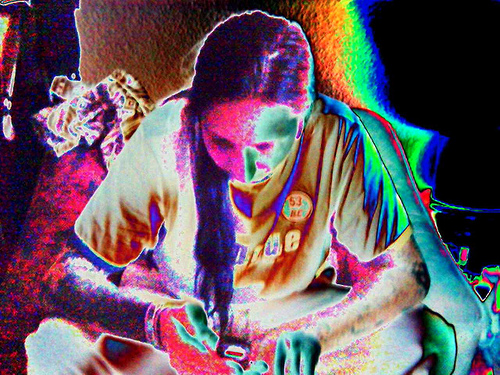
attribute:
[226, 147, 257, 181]
nose — large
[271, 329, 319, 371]
fingers — green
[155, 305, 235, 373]
hand — red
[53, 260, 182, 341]
arm — purple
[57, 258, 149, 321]
spots — blue, pink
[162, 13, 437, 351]
woman — long-haired, dark-haired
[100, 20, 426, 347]
woman — one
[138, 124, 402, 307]
shirt — white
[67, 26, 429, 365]
woman — one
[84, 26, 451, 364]
person — one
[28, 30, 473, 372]
image — distorted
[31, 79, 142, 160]
items — some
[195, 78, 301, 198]
face — female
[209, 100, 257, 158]
spot — pink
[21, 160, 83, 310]
item — pink, blue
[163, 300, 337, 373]
hands — blue, pale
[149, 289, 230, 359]
hand — human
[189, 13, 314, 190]
head — human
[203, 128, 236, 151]
eye — human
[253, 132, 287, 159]
eye — human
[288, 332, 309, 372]
finger — human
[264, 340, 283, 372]
finger — human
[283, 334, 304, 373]
finger — human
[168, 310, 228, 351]
finger — human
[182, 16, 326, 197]
head — human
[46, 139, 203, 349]
arm — human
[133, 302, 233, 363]
hand — human